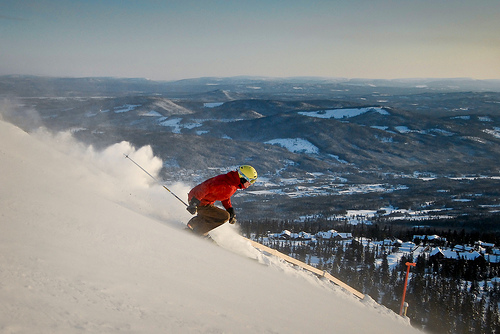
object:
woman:
[187, 165, 257, 240]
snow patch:
[298, 106, 390, 119]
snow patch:
[262, 138, 319, 154]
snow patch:
[147, 110, 210, 135]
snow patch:
[101, 104, 142, 113]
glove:
[187, 197, 201, 214]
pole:
[399, 264, 410, 316]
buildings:
[267, 228, 494, 260]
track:
[256, 247, 421, 334]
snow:
[264, 135, 319, 154]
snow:
[326, 205, 453, 225]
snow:
[297, 107, 390, 119]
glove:
[226, 207, 236, 224]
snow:
[0, 121, 423, 334]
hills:
[0, 75, 500, 178]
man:
[187, 165, 258, 238]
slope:
[0, 123, 416, 334]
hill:
[0, 119, 420, 333]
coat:
[188, 170, 246, 206]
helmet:
[238, 165, 257, 179]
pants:
[189, 207, 231, 236]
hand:
[187, 205, 197, 214]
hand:
[229, 218, 236, 224]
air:
[2, 3, 496, 85]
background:
[5, 2, 499, 250]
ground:
[0, 77, 500, 334]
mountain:
[0, 123, 416, 334]